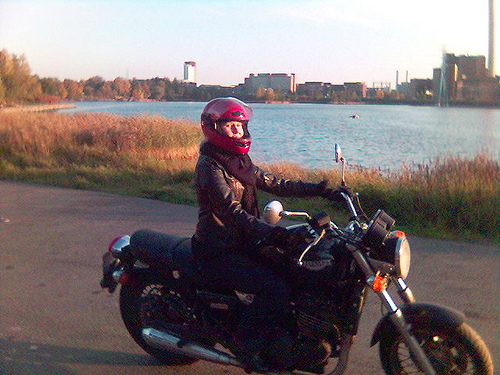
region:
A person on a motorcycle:
[147, 83, 462, 352]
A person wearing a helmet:
[195, 85, 263, 166]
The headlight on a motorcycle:
[359, 194, 431, 298]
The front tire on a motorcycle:
[375, 304, 479, 373]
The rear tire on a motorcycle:
[123, 271, 197, 359]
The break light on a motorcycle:
[99, 232, 131, 257]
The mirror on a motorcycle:
[262, 201, 308, 221]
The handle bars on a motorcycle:
[270, 145, 363, 256]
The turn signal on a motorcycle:
[354, 267, 398, 307]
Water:
[294, 101, 359, 135]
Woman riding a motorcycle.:
[178, 73, 350, 373]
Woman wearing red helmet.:
[197, 91, 257, 158]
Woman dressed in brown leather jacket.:
[187, 154, 324, 250]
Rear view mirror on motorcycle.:
[326, 138, 363, 190]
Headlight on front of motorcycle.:
[392, 234, 418, 281]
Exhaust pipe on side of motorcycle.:
[138, 325, 251, 374]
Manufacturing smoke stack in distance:
[475, 0, 499, 77]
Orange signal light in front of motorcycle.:
[366, 269, 393, 300]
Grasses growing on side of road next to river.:
[8, 101, 188, 197]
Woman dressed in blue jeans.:
[185, 233, 295, 353]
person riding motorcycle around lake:
[31, 36, 480, 359]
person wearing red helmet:
[176, 80, 268, 162]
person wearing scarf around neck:
[181, 121, 269, 223]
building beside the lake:
[153, 36, 496, 117]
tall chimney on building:
[481, 0, 498, 90]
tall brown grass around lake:
[6, 92, 489, 233]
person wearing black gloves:
[293, 167, 356, 251]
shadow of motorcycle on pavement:
[8, 313, 170, 374]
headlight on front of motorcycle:
[370, 211, 436, 298]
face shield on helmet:
[196, 88, 270, 129]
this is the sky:
[156, 4, 307, 46]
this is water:
[308, 115, 419, 147]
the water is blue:
[283, 105, 363, 150]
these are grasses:
[18, 105, 136, 157]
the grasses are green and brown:
[33, 113, 145, 191]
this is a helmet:
[188, 95, 263, 156]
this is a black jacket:
[191, 149, 308, 259]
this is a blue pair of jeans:
[193, 246, 295, 351]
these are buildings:
[270, 65, 377, 104]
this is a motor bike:
[106, 143, 483, 373]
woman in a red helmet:
[187, 95, 334, 368]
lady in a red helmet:
[185, 95, 334, 371]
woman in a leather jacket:
[172, 95, 327, 372]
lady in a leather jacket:
[189, 97, 345, 366]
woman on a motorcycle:
[190, 93, 356, 372]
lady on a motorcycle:
[180, 97, 360, 370]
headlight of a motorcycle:
[371, 230, 413, 279]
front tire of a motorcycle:
[380, 304, 492, 374]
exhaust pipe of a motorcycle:
[137, 321, 234, 366]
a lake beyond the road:
[17, 91, 499, 177]